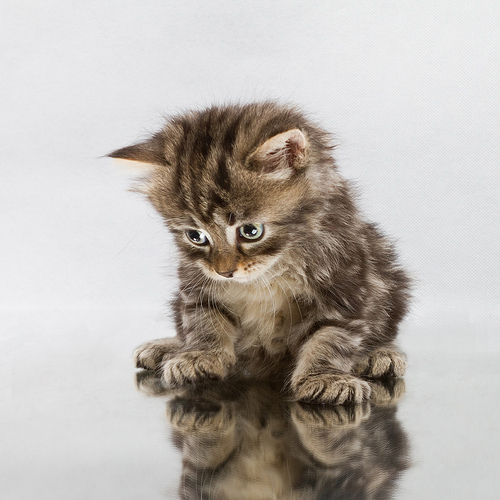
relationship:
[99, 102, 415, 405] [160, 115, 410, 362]
cat has fur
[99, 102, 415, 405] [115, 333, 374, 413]
cat has paws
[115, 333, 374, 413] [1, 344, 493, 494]
paws on table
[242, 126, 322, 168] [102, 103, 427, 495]
ear of cat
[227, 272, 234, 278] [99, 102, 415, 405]
nostril of cat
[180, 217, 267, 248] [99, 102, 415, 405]
eyes of cat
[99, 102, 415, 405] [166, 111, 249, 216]
cat has stripes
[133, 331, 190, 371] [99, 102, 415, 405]
leg of cat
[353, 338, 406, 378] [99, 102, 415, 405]
leg of cat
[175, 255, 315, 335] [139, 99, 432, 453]
whiskers on cat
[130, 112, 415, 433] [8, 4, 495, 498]
cat on picture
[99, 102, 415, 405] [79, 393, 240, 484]
cat in table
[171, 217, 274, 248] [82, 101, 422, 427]
eyes on cat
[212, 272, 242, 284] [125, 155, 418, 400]
mustache on cat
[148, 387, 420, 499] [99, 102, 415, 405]
reflection on cat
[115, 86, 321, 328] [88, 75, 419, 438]
head on cat